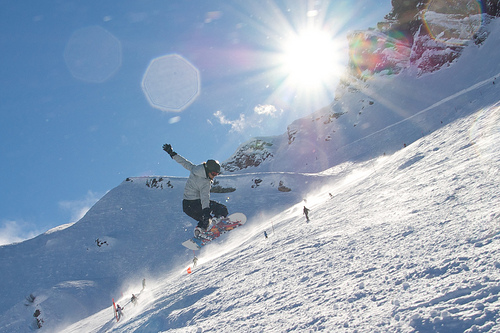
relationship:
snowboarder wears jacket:
[160, 143, 235, 235] [167, 148, 223, 218]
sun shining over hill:
[275, 35, 355, 95] [1, 1, 498, 331]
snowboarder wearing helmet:
[159, 137, 241, 237] [203, 156, 224, 176]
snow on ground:
[0, 10, 499, 330] [57, 77, 499, 331]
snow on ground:
[83, 105, 499, 331] [1, 0, 498, 328]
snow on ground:
[83, 105, 499, 331] [57, 77, 499, 331]